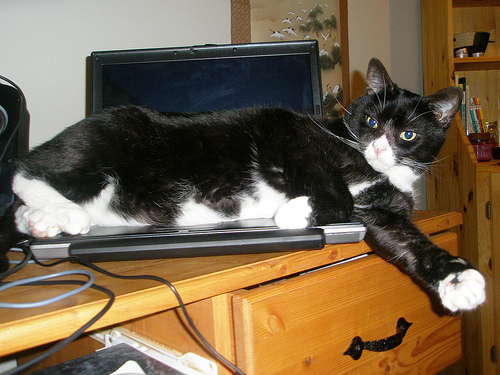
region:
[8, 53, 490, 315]
black and white cat lying on laptop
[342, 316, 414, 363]
black metal handle on wood desk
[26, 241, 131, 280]
black electrical cord coming from laptop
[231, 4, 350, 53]
painting of white birds behind desk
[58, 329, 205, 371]
keyboard draw on wooden desk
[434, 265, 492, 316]
white paw on black cat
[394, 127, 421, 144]
blue and yellow eyes on cat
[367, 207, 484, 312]
Extended black and white arm of a cat.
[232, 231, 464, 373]
Brown drawer with black handle.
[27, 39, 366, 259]
Silver and black laptop.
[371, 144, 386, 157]
Pink nose tip of a cat.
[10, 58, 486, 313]
A black and white cat.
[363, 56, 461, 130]
Left and right cat ears.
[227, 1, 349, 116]
A brown framed hanging picture with white birds on it.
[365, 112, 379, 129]
Right green and blue cat eye.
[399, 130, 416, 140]
Left green and blue cat eye.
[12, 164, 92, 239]
Back two white cat paws.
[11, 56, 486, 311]
black and white tuxedo cat laying on its side across a laptop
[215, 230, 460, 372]
wooden drawer with metal handle on a desk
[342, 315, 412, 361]
black metal handle on front of wooden drawer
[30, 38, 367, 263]
laptop sitting on top of a desk and has a cat lying across its keyboard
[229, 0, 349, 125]
wall hanging decoration found on a wall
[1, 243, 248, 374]
various cords on top of a desk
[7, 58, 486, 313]
black and white cat with dark blue eyes resting on a keyboard of a laptop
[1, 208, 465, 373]
wooden desk with light colored finish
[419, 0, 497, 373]
light stained wooden cabinet with shelves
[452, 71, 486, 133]
group of books standing in a wooden shelf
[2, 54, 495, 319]
A BLACK AND WHITE CAT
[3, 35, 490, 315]
A CAT LYING ON A LAPTOP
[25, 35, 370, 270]
A BLACK LAPTOP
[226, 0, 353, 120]
A PICTURE HANGING ON THE WALL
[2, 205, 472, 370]
A BROWN WOODEN DESK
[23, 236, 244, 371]
A BLACK LAPTOP CORD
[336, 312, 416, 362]
A BLACK DRAWER HANDLE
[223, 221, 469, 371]
A BROWN WOODEN DRAWER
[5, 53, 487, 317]
A CAT WITH BLUE EYES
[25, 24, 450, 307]
this is a cat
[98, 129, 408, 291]
the cat is black and white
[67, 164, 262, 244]
the stomach is white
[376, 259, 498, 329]
the paw is white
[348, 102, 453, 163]
the eyes are yellow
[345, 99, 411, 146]
the pupils are black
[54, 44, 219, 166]
this is a black laptop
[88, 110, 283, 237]
the cat is laying on a keyboard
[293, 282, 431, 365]
the handle is black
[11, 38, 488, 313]
cat reclined on laptop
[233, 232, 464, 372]
wood drawer with metal handle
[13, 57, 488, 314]
black and white fur on cat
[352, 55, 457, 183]
head of cat on laptop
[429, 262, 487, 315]
front paw of cat on laptop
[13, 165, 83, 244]
rear paws of cat on laptop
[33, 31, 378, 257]
the laptop the cat is on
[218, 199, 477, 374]
the drawer under the cat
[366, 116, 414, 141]
the eyes of the cat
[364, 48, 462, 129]
the ears of the cat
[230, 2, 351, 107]
picture of seagulls on wall behind cat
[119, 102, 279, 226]
the cats torso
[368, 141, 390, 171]
the nose and mouth of cat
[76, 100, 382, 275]
a cat laying inisde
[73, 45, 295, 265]
a cat on a laptop